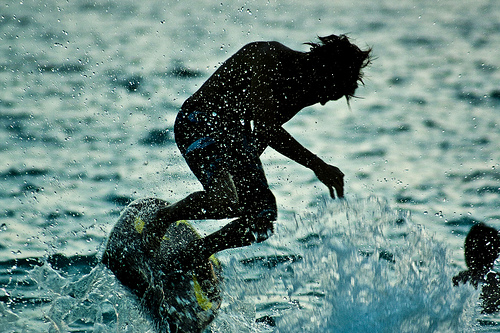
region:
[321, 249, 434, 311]
the waves are crashing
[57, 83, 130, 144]
droplets of the water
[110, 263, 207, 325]
wakeboard in the water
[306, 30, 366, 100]
hair of the person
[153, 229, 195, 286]
feet on the board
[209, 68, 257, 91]
back of the person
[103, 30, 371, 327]
silhouette of a person on a surfboard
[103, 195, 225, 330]
black and yellow surfboard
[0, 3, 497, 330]
blue green water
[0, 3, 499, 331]
sprinkles of water on the camera lens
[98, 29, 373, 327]
person with their hair sticking up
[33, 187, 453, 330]
splashing water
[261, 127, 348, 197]
arm sticking out toward the water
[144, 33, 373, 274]
person wearing a wet suit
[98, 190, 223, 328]
water spraying all over the surfboard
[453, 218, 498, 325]
a person in silhouette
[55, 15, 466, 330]
A person is in the ocean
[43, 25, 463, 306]
A person is doing some surfing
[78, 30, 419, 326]
A person is getting very wet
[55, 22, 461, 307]
A person is getting some exercise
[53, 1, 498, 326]
A person is doing a water sport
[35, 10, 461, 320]
A person is on a surfboard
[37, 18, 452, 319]
A person is on a vacation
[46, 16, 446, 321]
A person is on their day off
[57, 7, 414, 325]
A person is out in the daytime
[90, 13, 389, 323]
A person is enjoying their day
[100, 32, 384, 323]
the surfer is in silhouette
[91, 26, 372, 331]
the surfer has his knees bent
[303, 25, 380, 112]
the surfers hair is wet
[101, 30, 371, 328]
the surfer has his hair wet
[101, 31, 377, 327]
the water is splashing about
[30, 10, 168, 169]
bubbles are in the air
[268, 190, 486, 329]
a large splash of water on the left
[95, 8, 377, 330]
the surfer is on the water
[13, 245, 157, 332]
the surfboard is splashing water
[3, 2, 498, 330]
the water is blue in color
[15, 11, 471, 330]
a surfer on the waves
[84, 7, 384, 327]
this guy is riding the water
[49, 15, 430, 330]
the water is splashing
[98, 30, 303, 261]
water mist on the surfer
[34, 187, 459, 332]
this water is agitated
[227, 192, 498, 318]
the water is going everywhere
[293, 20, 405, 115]
this man's hair is wild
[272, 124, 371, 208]
his arm is extended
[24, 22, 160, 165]
the waves are going everywhere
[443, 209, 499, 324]
an object in the picture